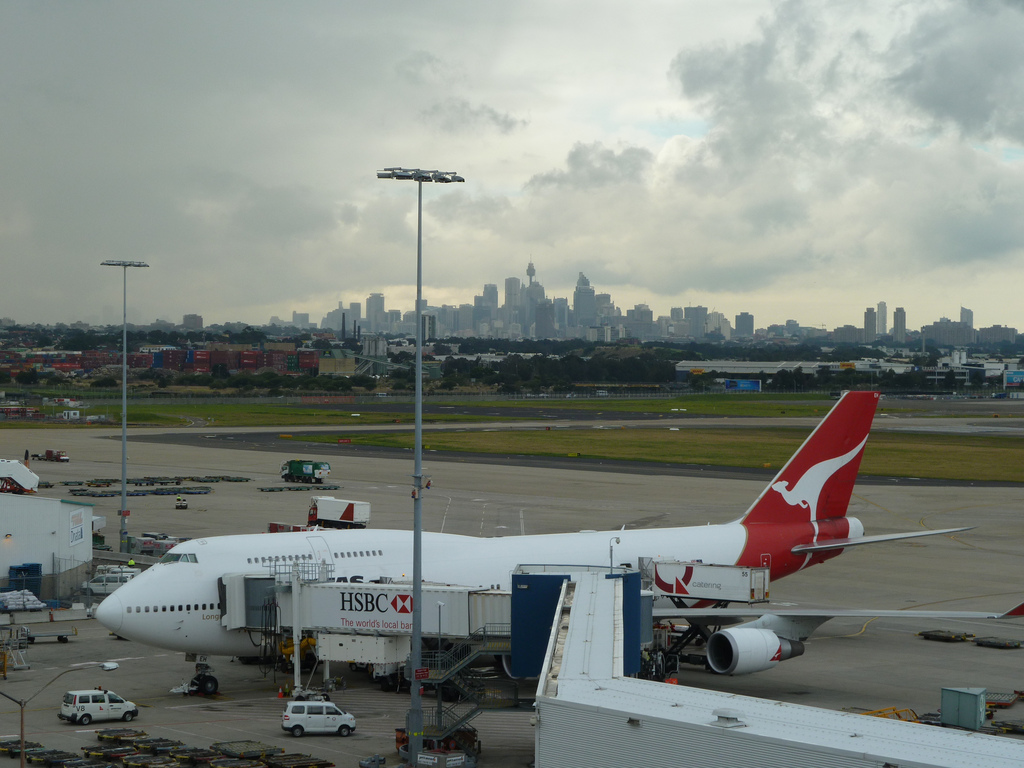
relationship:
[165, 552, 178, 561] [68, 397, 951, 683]
window on plane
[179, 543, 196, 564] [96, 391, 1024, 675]
window on airplane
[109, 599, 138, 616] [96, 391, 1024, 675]
window on airplane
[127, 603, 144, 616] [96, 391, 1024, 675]
window on airplane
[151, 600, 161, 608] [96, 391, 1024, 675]
window on airplane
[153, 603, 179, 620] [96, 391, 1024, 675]
window on airplane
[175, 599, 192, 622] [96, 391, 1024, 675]
window on airplane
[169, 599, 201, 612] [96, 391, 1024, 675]
window on airplane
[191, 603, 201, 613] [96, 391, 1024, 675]
window on airplane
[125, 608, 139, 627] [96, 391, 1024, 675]
window on airplane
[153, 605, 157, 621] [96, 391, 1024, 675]
window on airplane